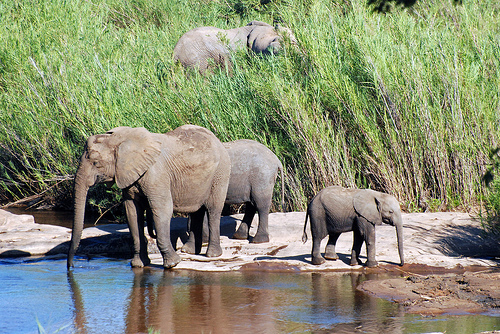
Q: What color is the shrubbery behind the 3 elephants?
A: Green.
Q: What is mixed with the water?
A: Mud.